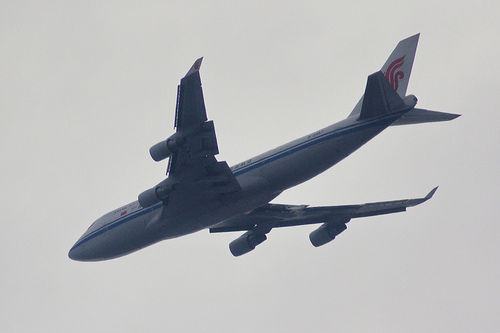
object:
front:
[67, 212, 111, 263]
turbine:
[150, 120, 215, 159]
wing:
[355, 34, 435, 106]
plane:
[67, 31, 464, 262]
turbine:
[310, 222, 346, 247]